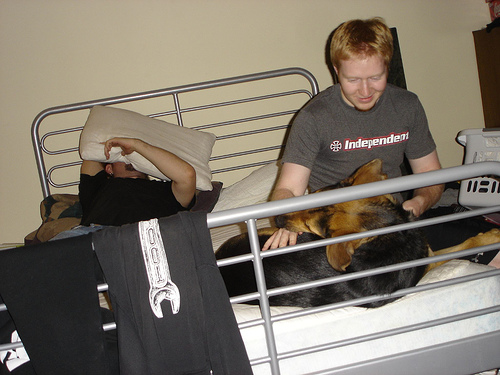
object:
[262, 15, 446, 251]
man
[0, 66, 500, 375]
bed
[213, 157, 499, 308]
dog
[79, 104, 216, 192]
pillow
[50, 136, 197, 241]
guy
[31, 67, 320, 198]
headboard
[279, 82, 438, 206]
shirt